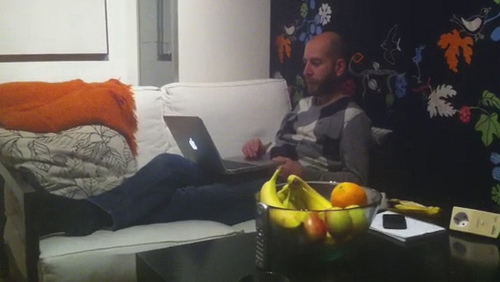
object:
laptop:
[162, 115, 284, 177]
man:
[23, 30, 376, 236]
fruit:
[322, 210, 360, 234]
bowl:
[255, 180, 386, 254]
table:
[132, 187, 500, 280]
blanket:
[0, 77, 141, 151]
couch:
[2, 76, 296, 279]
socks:
[22, 198, 101, 238]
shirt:
[269, 93, 373, 193]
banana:
[258, 168, 306, 228]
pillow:
[161, 79, 293, 169]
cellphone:
[382, 213, 407, 230]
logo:
[188, 138, 198, 151]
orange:
[330, 183, 368, 206]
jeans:
[80, 149, 296, 229]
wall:
[2, 1, 139, 88]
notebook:
[369, 208, 447, 241]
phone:
[251, 200, 273, 271]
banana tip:
[277, 165, 285, 171]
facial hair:
[300, 75, 337, 95]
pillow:
[0, 125, 131, 199]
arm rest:
[0, 157, 46, 281]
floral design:
[271, 1, 499, 206]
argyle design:
[287, 117, 342, 168]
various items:
[447, 205, 499, 236]